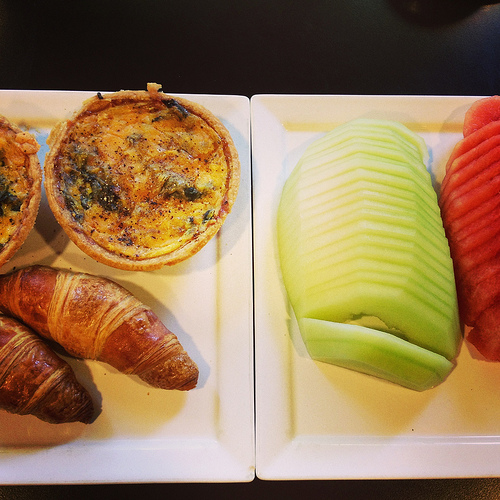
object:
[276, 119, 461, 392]
fruit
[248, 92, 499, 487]
plate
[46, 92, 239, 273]
quiche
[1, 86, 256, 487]
plate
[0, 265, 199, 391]
croissant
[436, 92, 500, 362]
melon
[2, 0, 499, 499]
table